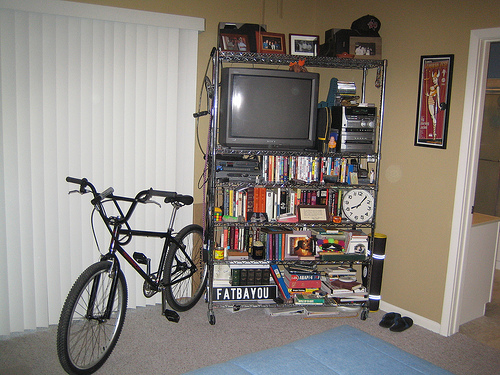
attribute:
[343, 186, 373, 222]
clock — round, white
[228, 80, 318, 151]
tv — black 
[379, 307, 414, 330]
shoes — black 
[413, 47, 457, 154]
picture — black, framed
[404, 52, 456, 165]
print — black, framed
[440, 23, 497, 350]
doorframe — white 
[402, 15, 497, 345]
frame — white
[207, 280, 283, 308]
sign — black , white 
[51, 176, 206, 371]
bicycle — large 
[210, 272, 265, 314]
sign — black 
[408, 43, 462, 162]
painting — red 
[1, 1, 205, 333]
blinds — vertical , white 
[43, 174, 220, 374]
bike — black 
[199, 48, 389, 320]
stand — silver, metal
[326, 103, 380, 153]
stereo — silver 